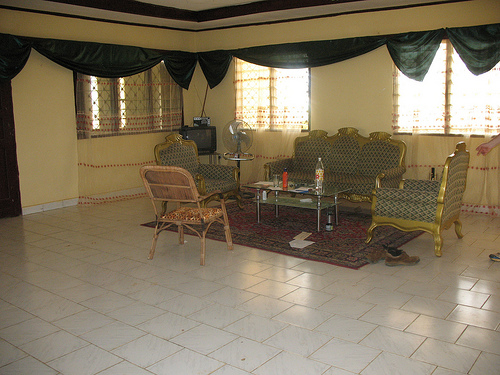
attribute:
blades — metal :
[234, 130, 249, 144]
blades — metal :
[224, 117, 239, 134]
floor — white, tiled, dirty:
[0, 190, 500, 373]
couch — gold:
[266, 126, 401, 218]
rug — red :
[229, 210, 406, 266]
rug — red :
[141, 197, 428, 269]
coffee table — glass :
[246, 170, 348, 237]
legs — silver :
[255, 201, 344, 231]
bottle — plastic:
[308, 152, 328, 201]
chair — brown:
[140, 162, 235, 266]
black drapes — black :
[77, 38, 224, 103]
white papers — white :
[288, 228, 314, 251]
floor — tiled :
[0, 170, 498, 372]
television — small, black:
[173, 120, 217, 154]